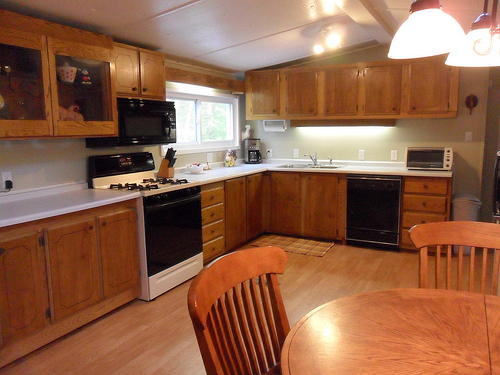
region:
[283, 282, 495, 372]
wooden kitchen table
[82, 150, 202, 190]
black and white cooktop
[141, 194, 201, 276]
oven as part of a stove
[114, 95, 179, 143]
microwave built into cabinets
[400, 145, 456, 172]
convection oven on countertop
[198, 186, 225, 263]
four kitchen drawers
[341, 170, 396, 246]
black dishwasher under counter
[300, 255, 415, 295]
hardwood floors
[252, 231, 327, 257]
rug on kitchen floor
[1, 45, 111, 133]
Wooden cabinets with windows in doors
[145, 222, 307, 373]
light brown wooden chair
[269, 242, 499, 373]
light brown round table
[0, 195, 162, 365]
wooden cabinets in the kitchen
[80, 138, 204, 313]
black and white stove top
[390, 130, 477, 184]
a white toaster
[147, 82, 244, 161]
a clear kitchen window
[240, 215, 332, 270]
a kitchen rug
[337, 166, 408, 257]
a black dishwasher in the kitchen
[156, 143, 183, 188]
a set of black knives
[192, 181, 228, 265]
a set of light colored drawers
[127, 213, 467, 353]
the chairs are wooden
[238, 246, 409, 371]
the chairs are wooden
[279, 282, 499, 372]
Wood table in the kitchen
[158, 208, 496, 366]
Two wooden chairs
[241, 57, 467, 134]
Row of five kitchen cabinets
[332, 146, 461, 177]
Toaster oven sitting on counter top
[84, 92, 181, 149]
Black microwave mounted under cabinets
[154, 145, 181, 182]
Wood knife block with knives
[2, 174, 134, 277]
White counter top above wood cabinets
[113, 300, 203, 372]
Wood floors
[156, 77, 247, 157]
Window to outside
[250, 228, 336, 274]
Rug on kitchen floor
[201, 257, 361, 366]
the table is wooden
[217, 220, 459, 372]
the table is wooden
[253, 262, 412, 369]
the table is wooden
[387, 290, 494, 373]
the table is wooden